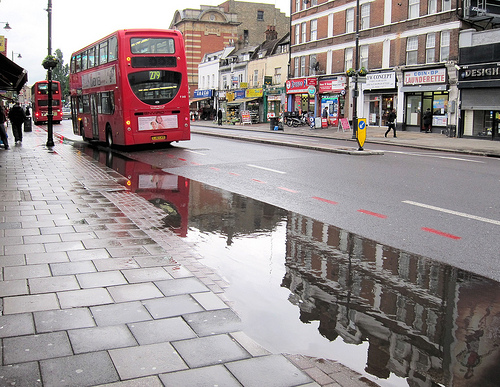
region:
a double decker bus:
[61, 23, 195, 152]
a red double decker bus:
[66, 25, 192, 151]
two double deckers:
[31, 25, 196, 152]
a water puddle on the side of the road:
[71, 144, 498, 385]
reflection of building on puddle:
[276, 208, 496, 385]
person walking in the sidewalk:
[382, 105, 401, 139]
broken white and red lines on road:
[183, 144, 498, 241]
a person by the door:
[418, 96, 434, 133]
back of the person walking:
[4, 98, 29, 145]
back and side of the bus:
[65, 25, 192, 152]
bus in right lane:
[51, 11, 195, 155]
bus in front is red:
[55, 19, 202, 170]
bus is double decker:
[55, 20, 194, 155]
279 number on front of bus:
[143, 65, 164, 86]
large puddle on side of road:
[65, 132, 495, 386]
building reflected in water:
[278, 209, 495, 386]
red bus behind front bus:
[24, 72, 71, 129]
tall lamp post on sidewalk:
[43, 4, 61, 145]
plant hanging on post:
[38, 53, 60, 78]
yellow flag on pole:
[354, 113, 371, 150]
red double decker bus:
[68, 25, 195, 154]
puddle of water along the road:
[87, 147, 477, 369]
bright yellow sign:
[356, 117, 368, 147]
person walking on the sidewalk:
[379, 101, 404, 141]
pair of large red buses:
[24, 28, 191, 152]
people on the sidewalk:
[0, 93, 28, 150]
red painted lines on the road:
[188, 158, 461, 260]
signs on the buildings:
[283, 59, 494, 88]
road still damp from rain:
[166, 107, 493, 274]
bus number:
[147, 67, 162, 78]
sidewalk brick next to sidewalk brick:
[1, 328, 76, 364]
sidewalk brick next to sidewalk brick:
[66, 323, 140, 352]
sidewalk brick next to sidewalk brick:
[125, 313, 201, 347]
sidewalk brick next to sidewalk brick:
[0, 359, 42, 384]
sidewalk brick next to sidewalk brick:
[39, 348, 120, 385]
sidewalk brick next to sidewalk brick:
[108, 342, 191, 379]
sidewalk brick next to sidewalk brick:
[168, 332, 249, 367]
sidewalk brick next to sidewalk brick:
[49, 259, 100, 275]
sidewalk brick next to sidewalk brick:
[76, 370, 163, 383]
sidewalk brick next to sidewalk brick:
[157, 362, 245, 384]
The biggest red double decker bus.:
[68, 29, 191, 148]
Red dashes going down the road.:
[157, 149, 461, 240]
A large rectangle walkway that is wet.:
[2, 129, 319, 385]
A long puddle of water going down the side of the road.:
[66, 139, 498, 385]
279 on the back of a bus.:
[147, 69, 162, 79]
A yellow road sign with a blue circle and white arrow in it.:
[354, 115, 366, 149]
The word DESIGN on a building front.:
[465, 68, 498, 77]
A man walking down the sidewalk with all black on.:
[6, 102, 28, 146]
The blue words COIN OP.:
[412, 67, 439, 76]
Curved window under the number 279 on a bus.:
[131, 81, 183, 106]